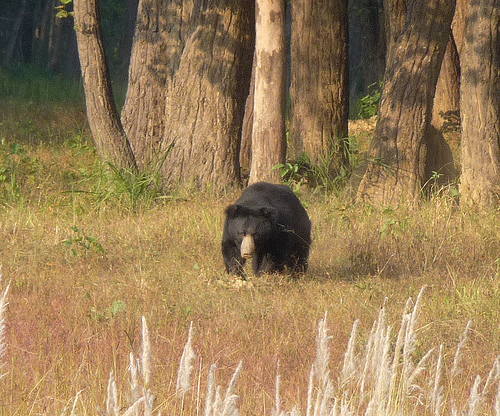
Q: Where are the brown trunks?
A: Behind bear.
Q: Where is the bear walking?
A: Tall dry grass.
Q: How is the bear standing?
A: All four legs.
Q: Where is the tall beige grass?
A: Bottom front.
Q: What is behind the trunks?
A: More trees.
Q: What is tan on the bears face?
A: Nose.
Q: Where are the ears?
A: Top of bear's head.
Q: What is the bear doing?
A: Walking.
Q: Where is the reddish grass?
A: Front of bear.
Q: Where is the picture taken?
A: A field.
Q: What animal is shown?
A: A bear.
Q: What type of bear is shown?
A: Black.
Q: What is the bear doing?
A: Walking.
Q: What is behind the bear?
A: Trees.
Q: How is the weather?
A: Sunny.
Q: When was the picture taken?
A: Afternoon.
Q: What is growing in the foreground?
A: White grass.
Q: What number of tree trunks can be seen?
A: Eight.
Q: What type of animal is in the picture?
A: Bear.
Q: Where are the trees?
A: Behind the bear.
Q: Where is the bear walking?
A: Grass.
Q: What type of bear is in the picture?
A: Black bear.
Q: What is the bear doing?
A: Walking.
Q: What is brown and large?
A: Tree.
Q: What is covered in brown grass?
A: Field.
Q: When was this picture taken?
A: Daytime.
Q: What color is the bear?
A: Black.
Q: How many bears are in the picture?
A: One.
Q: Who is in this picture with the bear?
A: No one.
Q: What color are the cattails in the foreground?
A: White.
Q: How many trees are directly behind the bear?
A: Eight.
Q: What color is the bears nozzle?
A: Tan.